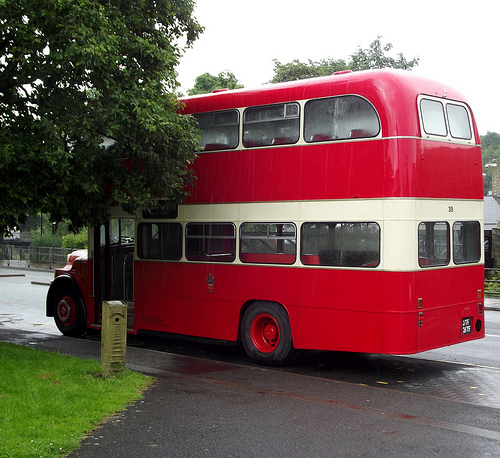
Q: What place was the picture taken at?
A: It was taken at the roadway.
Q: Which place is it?
A: It is a roadway.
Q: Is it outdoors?
A: Yes, it is outdoors.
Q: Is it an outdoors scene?
A: Yes, it is outdoors.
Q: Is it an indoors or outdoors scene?
A: It is outdoors.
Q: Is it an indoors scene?
A: No, it is outdoors.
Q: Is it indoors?
A: No, it is outdoors.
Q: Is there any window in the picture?
A: Yes, there is a window.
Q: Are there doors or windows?
A: Yes, there is a window.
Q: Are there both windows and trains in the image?
A: No, there is a window but no trains.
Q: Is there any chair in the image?
A: No, there are no chairs.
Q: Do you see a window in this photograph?
A: Yes, there is a window.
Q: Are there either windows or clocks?
A: Yes, there is a window.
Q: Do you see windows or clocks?
A: Yes, there is a window.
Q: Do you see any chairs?
A: No, there are no chairs.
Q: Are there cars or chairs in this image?
A: No, there are no chairs or cars.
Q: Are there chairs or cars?
A: No, there are no chairs or cars.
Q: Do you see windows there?
A: Yes, there is a window.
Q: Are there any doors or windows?
A: Yes, there is a window.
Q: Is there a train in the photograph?
A: No, there are no trains.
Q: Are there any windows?
A: Yes, there is a window.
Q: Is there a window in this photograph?
A: Yes, there is a window.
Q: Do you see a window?
A: Yes, there is a window.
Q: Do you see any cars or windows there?
A: Yes, there is a window.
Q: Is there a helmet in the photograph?
A: No, there are no helmets.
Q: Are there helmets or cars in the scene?
A: No, there are no helmets or cars.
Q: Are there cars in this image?
A: No, there are no cars.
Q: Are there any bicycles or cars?
A: No, there are no cars or bicycles.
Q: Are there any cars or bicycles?
A: No, there are no cars or bicycles.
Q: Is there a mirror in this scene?
A: No, there are no mirrors.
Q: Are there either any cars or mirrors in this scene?
A: No, there are no mirrors or cars.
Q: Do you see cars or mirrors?
A: No, there are no mirrors or cars.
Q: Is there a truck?
A: No, there are no trucks.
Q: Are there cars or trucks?
A: No, there are no trucks or cars.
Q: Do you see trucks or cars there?
A: No, there are no trucks or cars.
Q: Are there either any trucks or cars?
A: No, there are no trucks or cars.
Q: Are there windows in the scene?
A: Yes, there is a window.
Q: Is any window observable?
A: Yes, there is a window.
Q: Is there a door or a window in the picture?
A: Yes, there is a window.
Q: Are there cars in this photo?
A: No, there are no cars.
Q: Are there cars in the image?
A: No, there are no cars.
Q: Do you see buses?
A: Yes, there is a bus.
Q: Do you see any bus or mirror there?
A: Yes, there is a bus.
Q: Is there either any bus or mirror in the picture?
A: Yes, there is a bus.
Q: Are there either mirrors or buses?
A: Yes, there is a bus.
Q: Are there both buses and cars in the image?
A: No, there is a bus but no cars.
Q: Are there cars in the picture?
A: No, there are no cars.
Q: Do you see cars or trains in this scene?
A: No, there are no cars or trains.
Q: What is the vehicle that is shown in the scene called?
A: The vehicle is a bus.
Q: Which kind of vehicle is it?
A: The vehicle is a bus.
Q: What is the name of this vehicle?
A: This is a bus.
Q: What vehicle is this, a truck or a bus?
A: This is a bus.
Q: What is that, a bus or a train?
A: That is a bus.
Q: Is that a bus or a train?
A: That is a bus.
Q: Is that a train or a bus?
A: That is a bus.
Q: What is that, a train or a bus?
A: That is a bus.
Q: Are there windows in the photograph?
A: Yes, there is a window.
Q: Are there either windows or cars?
A: Yes, there is a window.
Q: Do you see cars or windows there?
A: Yes, there is a window.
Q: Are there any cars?
A: No, there are no cars.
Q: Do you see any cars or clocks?
A: No, there are no cars or clocks.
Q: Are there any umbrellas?
A: No, there are no umbrellas.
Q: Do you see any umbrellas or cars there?
A: No, there are no umbrellas or cars.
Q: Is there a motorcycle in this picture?
A: No, there are no motorcycles.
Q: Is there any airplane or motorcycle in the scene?
A: No, there are no motorcycles or airplanes.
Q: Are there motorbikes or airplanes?
A: No, there are no motorbikes or airplanes.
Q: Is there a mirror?
A: No, there are no mirrors.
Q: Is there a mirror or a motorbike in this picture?
A: No, there are no mirrors or motorcycles.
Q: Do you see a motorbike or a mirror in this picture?
A: No, there are no mirrors or motorcycles.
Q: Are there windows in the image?
A: Yes, there is a window.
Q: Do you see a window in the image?
A: Yes, there is a window.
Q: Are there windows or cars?
A: Yes, there is a window.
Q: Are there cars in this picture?
A: No, there are no cars.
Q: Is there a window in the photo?
A: Yes, there is a window.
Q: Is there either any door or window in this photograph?
A: Yes, there is a window.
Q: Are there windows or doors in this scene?
A: Yes, there is a window.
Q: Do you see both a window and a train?
A: No, there is a window but no trains.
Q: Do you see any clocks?
A: No, there are no clocks.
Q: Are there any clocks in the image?
A: No, there are no clocks.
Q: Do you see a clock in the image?
A: No, there are no clocks.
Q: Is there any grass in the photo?
A: Yes, there is grass.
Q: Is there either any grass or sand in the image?
A: Yes, there is grass.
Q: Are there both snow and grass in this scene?
A: No, there is grass but no snow.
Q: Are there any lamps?
A: No, there are no lamps.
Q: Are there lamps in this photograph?
A: No, there are no lamps.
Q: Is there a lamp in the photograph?
A: No, there are no lamps.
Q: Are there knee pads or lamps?
A: No, there are no lamps or knee pads.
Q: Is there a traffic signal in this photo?
A: No, there are no traffic lights.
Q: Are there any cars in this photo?
A: No, there are no cars.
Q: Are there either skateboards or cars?
A: No, there are no cars or skateboards.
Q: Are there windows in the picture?
A: Yes, there is a window.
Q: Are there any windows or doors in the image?
A: Yes, there is a window.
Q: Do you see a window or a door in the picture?
A: Yes, there is a window.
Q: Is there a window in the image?
A: Yes, there is a window.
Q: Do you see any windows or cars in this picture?
A: Yes, there is a window.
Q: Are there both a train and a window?
A: No, there is a window but no trains.